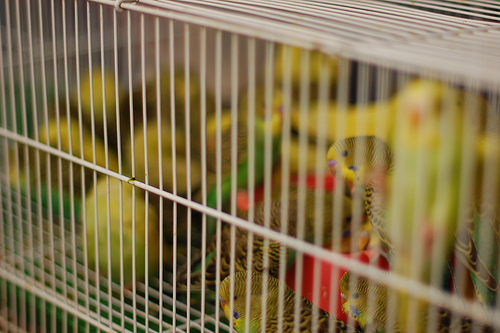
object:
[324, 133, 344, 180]
yellow beak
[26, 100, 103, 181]
birds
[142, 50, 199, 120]
birds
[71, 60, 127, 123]
birds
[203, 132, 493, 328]
chics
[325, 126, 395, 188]
head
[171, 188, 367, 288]
bird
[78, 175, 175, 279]
bird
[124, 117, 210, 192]
bird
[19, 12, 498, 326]
bird cage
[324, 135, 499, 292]
bird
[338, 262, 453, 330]
bird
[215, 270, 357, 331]
bird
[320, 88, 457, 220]
giraffe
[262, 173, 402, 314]
dish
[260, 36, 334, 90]
birds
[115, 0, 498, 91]
top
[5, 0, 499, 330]
side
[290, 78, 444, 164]
bird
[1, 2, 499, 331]
cage